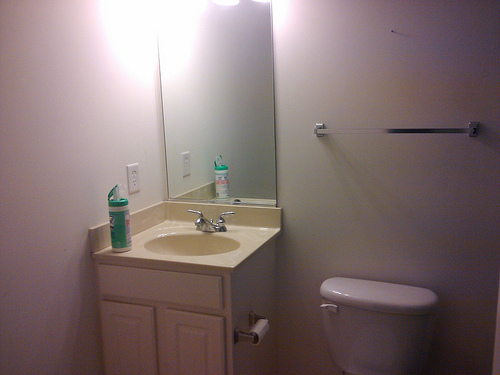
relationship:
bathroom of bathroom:
[0, 0, 499, 374] [101, 172, 481, 342]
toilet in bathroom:
[311, 270, 459, 373] [101, 172, 481, 342]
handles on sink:
[184, 202, 234, 228] [86, 187, 286, 290]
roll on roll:
[250, 318, 270, 346] [238, 313, 278, 346]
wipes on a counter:
[101, 182, 140, 259] [86, 187, 286, 290]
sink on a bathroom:
[86, 187, 286, 290] [101, 172, 481, 342]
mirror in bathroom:
[150, 2, 283, 211] [101, 172, 481, 342]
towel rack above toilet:
[308, 117, 481, 146] [311, 270, 459, 373]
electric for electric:
[126, 161, 141, 195] [131, 167, 139, 188]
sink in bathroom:
[86, 187, 286, 290] [101, 172, 481, 342]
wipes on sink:
[101, 182, 140, 259] [86, 187, 286, 290]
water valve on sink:
[184, 205, 235, 236] [86, 187, 286, 290]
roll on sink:
[250, 318, 270, 346] [86, 187, 286, 290]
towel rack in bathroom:
[308, 117, 481, 146] [101, 172, 481, 342]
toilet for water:
[318, 276, 441, 375] [360, 310, 384, 317]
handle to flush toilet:
[318, 300, 340, 315] [311, 270, 459, 373]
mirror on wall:
[150, 2, 283, 211] [282, 5, 485, 130]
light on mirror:
[105, 3, 192, 38] [150, 2, 283, 211]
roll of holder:
[250, 318, 270, 346] [233, 309, 249, 344]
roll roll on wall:
[250, 318, 270, 346] [282, 5, 485, 130]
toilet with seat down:
[311, 270, 459, 373] [251, 349, 362, 374]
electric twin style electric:
[131, 167, 139, 188] [126, 161, 141, 195]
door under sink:
[101, 297, 230, 373] [86, 187, 286, 290]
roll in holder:
[250, 318, 270, 346] [233, 309, 249, 344]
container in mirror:
[107, 211, 132, 252] [150, 2, 283, 211]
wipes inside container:
[101, 182, 140, 259] [107, 211, 132, 252]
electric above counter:
[126, 161, 141, 195] [146, 226, 235, 255]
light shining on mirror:
[105, 3, 192, 38] [150, 2, 283, 211]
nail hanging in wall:
[387, 28, 401, 37] [282, 5, 485, 130]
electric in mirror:
[126, 161, 141, 195] [150, 2, 283, 211]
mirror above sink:
[150, 2, 283, 211] [86, 187, 286, 290]